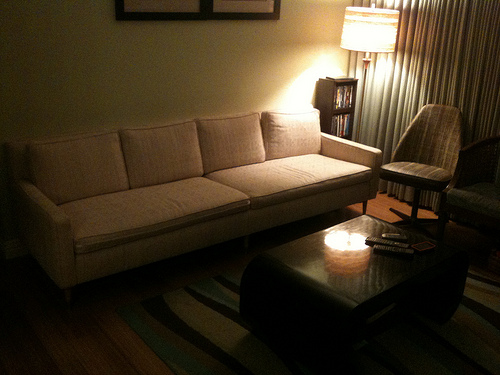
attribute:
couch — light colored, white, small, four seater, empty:
[4, 103, 382, 301]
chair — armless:
[379, 101, 464, 241]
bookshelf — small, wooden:
[315, 75, 357, 144]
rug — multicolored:
[114, 264, 498, 374]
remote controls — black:
[366, 231, 436, 257]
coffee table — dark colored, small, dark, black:
[238, 213, 467, 357]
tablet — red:
[412, 240, 434, 253]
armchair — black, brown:
[435, 133, 499, 242]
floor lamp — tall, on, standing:
[338, 5, 401, 143]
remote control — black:
[371, 243, 415, 258]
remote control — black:
[364, 234, 409, 249]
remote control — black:
[382, 231, 408, 241]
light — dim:
[259, 47, 440, 221]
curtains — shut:
[345, 0, 499, 229]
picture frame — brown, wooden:
[112, 0, 281, 20]